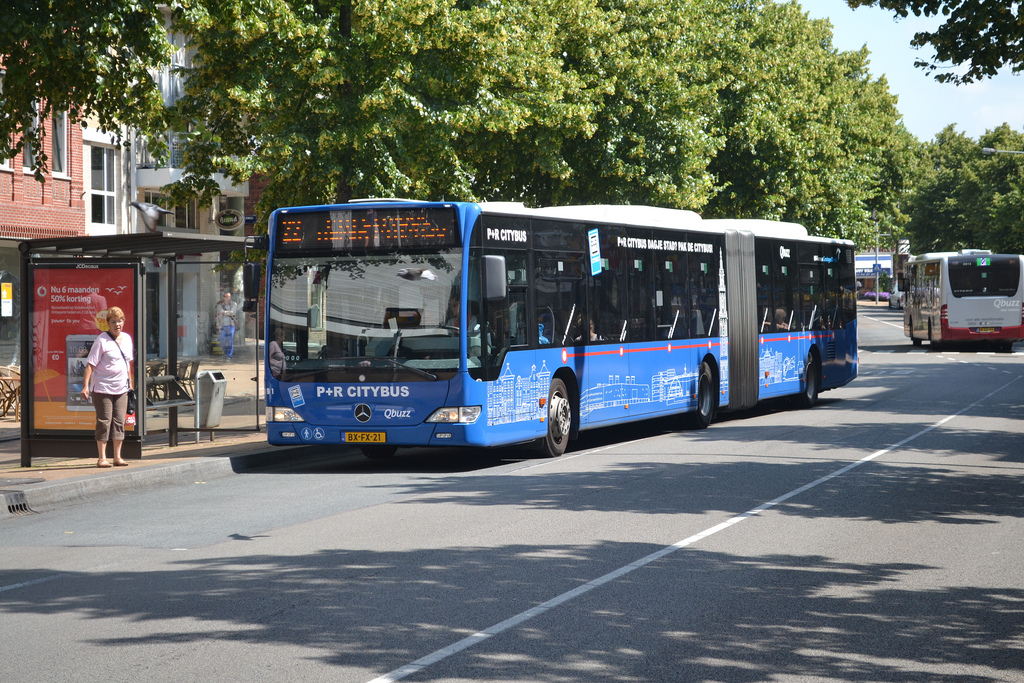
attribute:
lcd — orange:
[309, 200, 505, 264]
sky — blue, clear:
[857, 36, 1022, 151]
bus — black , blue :
[264, 199, 854, 453]